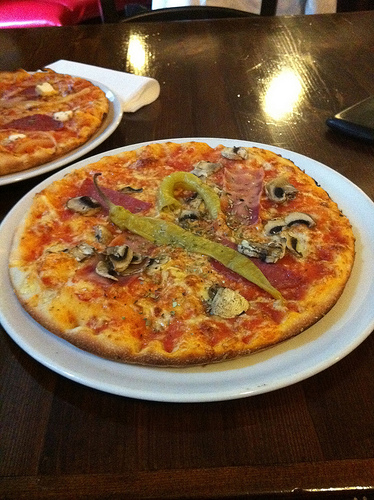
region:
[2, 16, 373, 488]
pizza on a table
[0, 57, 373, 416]
two pizzas are on a table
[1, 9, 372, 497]
the table is a dark colored wood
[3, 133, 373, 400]
the pizza is on a white plate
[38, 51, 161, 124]
a white napkin is tucked under the plate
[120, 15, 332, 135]
light is reflecting off of the table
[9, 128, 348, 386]
the pizza has mushrooms on it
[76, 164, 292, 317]
whole green peppers are in the center of the pizza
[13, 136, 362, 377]
the pizza has not been cut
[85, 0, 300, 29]
no one is sitting at the table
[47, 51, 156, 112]
a folded napkin tucked under a plate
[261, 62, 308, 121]
light reflecting on a table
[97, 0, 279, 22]
a chair at a table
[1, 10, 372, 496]
a dark brown table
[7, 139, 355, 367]
a pizza on a plate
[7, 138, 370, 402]
a large round white plate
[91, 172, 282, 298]
a long skinny pepper on a plate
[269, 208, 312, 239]
a sliced mushroom on a pizza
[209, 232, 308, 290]
a large half slice of pepperoni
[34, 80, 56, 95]
a white chunk of cheese on a pizza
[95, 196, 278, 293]
A long green pepper on the pizza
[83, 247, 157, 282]
Mushrooms on the pizza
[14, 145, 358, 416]
A pizza on a white plate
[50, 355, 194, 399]
A clean white plate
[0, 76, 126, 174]
Another pizza behind the front one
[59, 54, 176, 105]
White napkins by the pizza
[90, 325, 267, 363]
A thin pizza crust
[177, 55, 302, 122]
A brown wooden table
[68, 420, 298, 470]
A wooden table beneath the plate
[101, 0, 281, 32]
A wooden chair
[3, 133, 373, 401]
a pizza is on a white plate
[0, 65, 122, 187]
a small pizza is on a white plate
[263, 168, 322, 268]
sliced mushrooms are on the pizza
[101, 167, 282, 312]
green peppers are on the pizza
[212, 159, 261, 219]
pepperoni is on the pizza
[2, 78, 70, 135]
chunks of cheese are on the small pizza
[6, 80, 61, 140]
slices of pepperoni are on the small pizza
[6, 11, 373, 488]
the pizzas are on a dark wood table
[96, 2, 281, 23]
a wooden chair is at the table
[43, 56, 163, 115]
white napkins are on the table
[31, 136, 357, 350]
large pizza on table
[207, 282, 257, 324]
mushroom on top of pizza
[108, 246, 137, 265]
mushroom on top of pizza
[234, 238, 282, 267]
mushroom on top of pizza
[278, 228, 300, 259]
mushroom on top of pizza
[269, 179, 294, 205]
mushroom on top of pizza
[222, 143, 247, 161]
mushroom on top of pizza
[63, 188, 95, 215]
mushroom on top of pizza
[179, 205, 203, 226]
mushroom on top of pizza